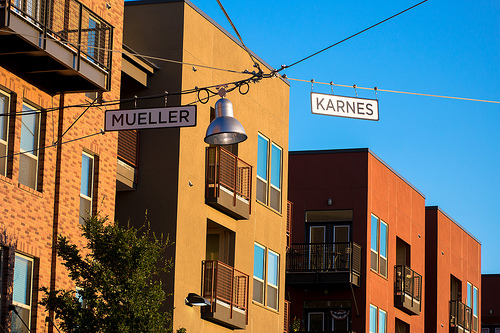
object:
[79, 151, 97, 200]
window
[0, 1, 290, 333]
building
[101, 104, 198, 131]
sign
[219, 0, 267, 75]
wire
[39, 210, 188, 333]
tree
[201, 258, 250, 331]
balcony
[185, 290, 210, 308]
light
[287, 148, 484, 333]
structure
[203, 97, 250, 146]
lamp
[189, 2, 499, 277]
sky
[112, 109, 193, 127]
writing